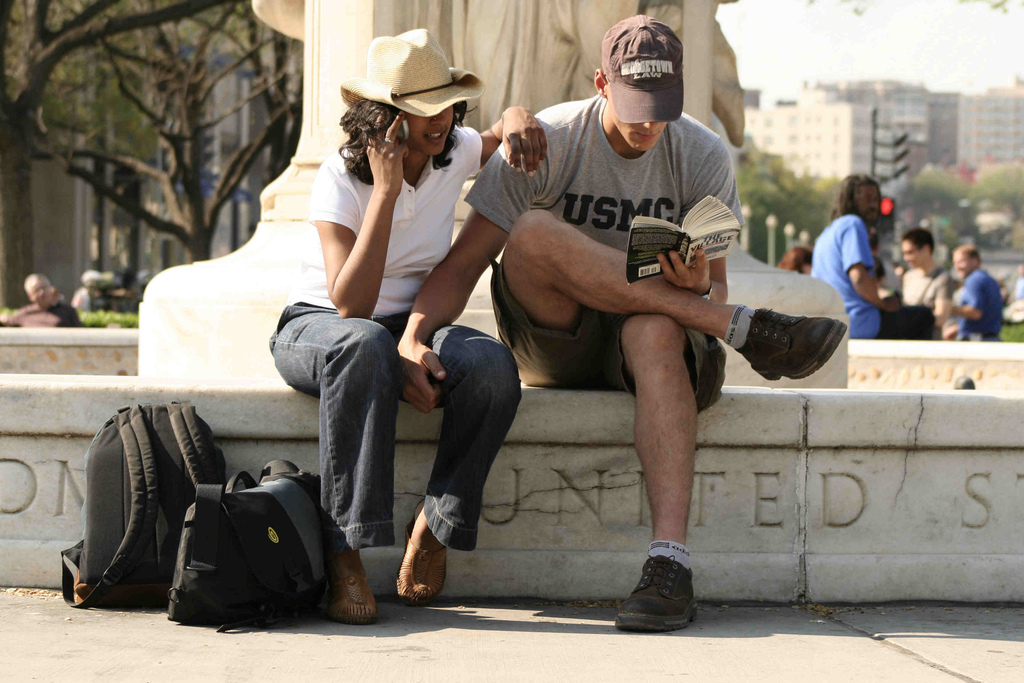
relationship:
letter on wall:
[628, 471, 657, 524] [7, 366, 1021, 615]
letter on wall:
[549, 467, 612, 528] [7, 366, 1021, 615]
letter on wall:
[735, 444, 800, 537] [0, 353, 1022, 591]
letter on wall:
[804, 454, 871, 537] [7, 366, 1021, 615]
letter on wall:
[948, 448, 1007, 557] [7, 366, 1021, 615]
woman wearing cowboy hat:
[269, 24, 548, 619] [339, 24, 482, 118]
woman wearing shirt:
[269, 24, 548, 619] [295, 122, 483, 315]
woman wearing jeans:
[269, 24, 548, 619] [277, 298, 533, 551]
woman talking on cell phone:
[269, 24, 548, 619] [386, 113, 413, 144]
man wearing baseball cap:
[395, 16, 849, 628] [600, 14, 687, 118]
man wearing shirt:
[395, 16, 849, 628] [465, 90, 742, 276]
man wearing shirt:
[807, 168, 936, 348] [807, 213, 886, 339]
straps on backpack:
[86, 396, 205, 597] [62, 402, 235, 610]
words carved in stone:
[0, 450, 1024, 530] [4, 374, 1022, 604]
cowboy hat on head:
[339, 24, 482, 118] [334, 93, 468, 174]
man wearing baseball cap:
[395, 16, 849, 628] [595, 3, 691, 126]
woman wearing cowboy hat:
[269, 24, 548, 619] [337, 23, 489, 120]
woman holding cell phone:
[269, 24, 548, 619] [383, 109, 414, 149]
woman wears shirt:
[269, 24, 548, 619] [309, 122, 502, 326]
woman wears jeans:
[259, 24, 552, 627] [277, 298, 533, 551]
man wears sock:
[389, 10, 862, 640] [639, 525, 694, 562]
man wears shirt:
[806, 168, 899, 343] [806, 213, 884, 339]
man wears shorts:
[389, 10, 862, 640] [486, 250, 739, 417]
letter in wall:
[551, 458, 606, 528] [0, 384, 1020, 596]